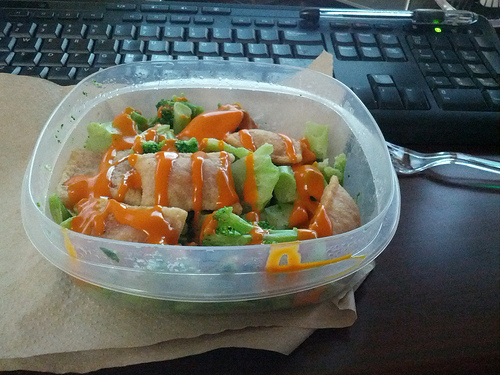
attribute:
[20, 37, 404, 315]
bowl — clear, white, plastic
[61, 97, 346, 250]
broccoli — green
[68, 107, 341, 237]
dressing — orange, french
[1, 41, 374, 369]
napkin — white, beige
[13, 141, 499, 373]
desk — wood, brown, wooden, black, burgundy wood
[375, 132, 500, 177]
fork — clear, plastic, transparent, disposable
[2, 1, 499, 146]
keyboard — black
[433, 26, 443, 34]
light — green